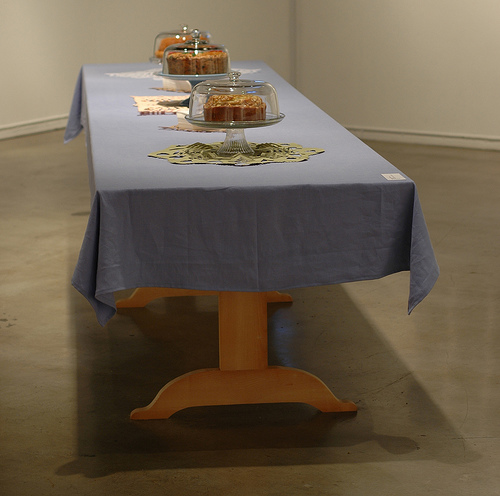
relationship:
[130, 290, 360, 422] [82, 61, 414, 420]
leg on table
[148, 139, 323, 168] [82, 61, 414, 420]
doily on table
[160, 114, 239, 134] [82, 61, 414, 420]
mat on table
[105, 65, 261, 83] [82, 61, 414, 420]
doily on table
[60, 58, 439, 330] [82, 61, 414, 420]
tablecloth on table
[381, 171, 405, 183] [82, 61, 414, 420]
card on table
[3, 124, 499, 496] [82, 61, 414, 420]
floor under table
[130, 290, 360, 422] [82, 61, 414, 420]
leg of table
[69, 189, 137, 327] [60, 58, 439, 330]
corner of tablecloth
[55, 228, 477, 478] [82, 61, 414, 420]
shadow under table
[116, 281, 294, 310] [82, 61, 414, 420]
leg of table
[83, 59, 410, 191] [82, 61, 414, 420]
top of table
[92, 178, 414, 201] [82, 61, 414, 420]
edge of table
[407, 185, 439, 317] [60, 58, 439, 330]
corner on tablecloth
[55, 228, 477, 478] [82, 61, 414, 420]
shadow of table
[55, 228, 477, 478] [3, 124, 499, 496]
shadow on floor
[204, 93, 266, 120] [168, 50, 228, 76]
cake next to cake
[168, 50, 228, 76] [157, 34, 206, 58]
cake next to cake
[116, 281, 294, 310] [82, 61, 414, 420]
leg on table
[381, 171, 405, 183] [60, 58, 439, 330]
card on tablecloth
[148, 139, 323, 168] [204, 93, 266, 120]
doily under cake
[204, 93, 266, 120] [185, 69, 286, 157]
cake in cake dish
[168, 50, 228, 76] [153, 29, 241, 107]
cake in cake dish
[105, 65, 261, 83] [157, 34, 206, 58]
doily under cake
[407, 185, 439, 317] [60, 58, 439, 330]
corner of tablecloth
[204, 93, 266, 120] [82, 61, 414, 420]
cake on table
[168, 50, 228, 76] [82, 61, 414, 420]
cake on table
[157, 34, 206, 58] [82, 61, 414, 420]
cake on table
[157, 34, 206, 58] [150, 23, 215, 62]
cake in cake dish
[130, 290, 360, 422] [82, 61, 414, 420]
leg under table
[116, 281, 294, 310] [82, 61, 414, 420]
leg under table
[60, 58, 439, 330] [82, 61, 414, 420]
tablecloth hanging on table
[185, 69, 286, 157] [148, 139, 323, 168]
cake dish on doily